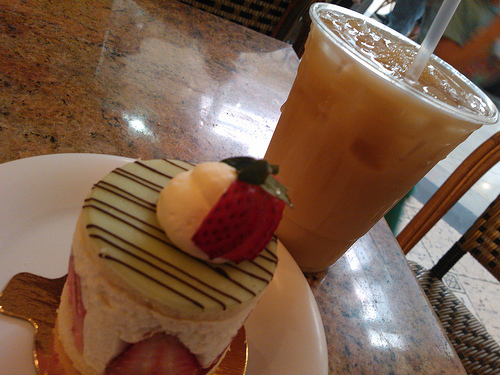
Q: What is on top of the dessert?
A: A Strawberry.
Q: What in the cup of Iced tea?
A: A straw.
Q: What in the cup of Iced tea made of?
A: Plastic.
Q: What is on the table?
A: A dessert plate and a drink of Ice tea.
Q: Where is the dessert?
A: On a white plate.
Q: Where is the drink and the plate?
A: On top of the table.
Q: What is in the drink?
A: Ice tea and Ice.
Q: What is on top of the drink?
A: Ice and a straw.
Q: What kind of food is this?
A: Dessert.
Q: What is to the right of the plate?
A: Drink in plastic cup.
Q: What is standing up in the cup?
A: Straw.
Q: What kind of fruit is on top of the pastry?
A: Strawberry.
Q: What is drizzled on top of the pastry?
A: Chocolate.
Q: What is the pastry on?
A: White plate.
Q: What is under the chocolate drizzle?
A: Yellow frosting.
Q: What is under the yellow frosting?
A: Whipped cream.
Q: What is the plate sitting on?
A: Granite table top.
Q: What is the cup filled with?
A: Liquid.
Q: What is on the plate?
A: Dessert.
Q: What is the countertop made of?
A: Marble.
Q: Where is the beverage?
A: Behind the food.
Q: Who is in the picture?
A: No one.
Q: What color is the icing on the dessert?
A: Green.